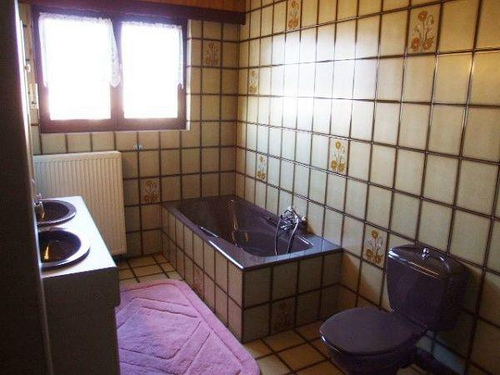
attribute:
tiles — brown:
[37, 1, 491, 368]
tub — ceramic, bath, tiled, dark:
[159, 181, 345, 368]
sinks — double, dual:
[35, 187, 128, 374]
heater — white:
[29, 147, 138, 267]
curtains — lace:
[24, 19, 197, 96]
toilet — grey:
[311, 238, 488, 374]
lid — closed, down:
[309, 306, 448, 360]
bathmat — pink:
[78, 283, 269, 374]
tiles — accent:
[320, 132, 358, 181]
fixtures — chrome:
[271, 201, 311, 269]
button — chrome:
[423, 249, 429, 255]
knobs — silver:
[284, 205, 306, 228]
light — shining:
[45, 36, 178, 111]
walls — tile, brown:
[21, 16, 490, 322]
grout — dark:
[326, 124, 493, 176]